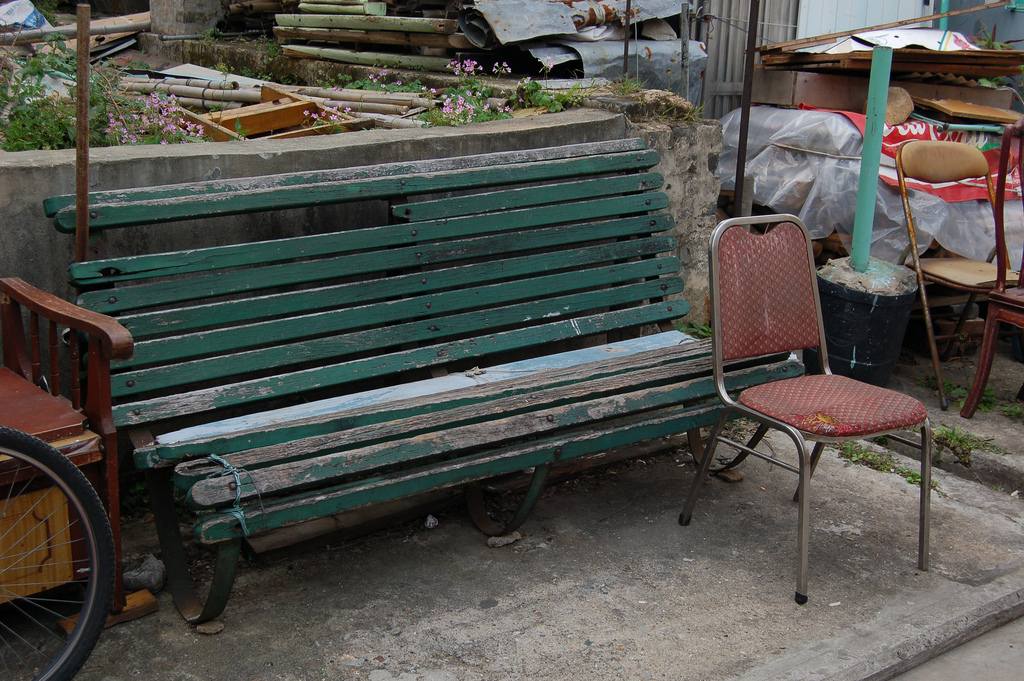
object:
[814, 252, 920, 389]
bucket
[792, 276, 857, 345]
ground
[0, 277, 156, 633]
chair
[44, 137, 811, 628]
bench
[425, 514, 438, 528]
crumpled paper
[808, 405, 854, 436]
seat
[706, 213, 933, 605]
chair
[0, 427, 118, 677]
tire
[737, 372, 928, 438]
seat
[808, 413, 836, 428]
tear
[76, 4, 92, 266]
pole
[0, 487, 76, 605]
spokes